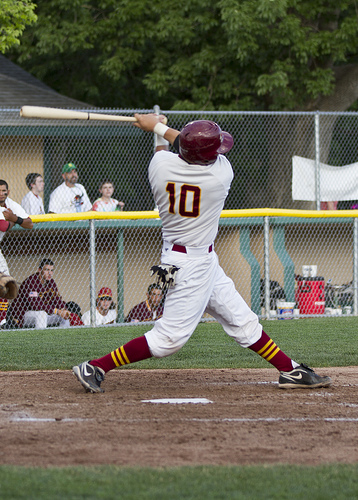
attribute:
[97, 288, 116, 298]
cap — red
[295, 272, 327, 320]
cooler — red 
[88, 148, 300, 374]
uniform — white, red, and yellow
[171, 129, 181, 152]
wristband — black 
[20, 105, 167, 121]
bat — wooden 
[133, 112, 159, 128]
hand — man's 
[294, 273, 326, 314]
cooler — black , red 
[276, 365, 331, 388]
baseball cleat — white baseball , black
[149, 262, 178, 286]
gloves — black, white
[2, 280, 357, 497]
field — baseball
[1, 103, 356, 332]
fence — chain link, silver, link, chain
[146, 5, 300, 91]
tree — large, green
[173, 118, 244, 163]
hat — red, hard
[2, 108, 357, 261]
fence — chain link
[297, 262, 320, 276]
cups — white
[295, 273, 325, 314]
water cooler — red, black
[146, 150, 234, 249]
jersey — baseball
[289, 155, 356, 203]
banner — white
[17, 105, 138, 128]
bat — light-colored, wooden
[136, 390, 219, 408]
plate — white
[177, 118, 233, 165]
helmet — burgundy,  dark red, for batting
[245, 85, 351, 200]
trunk — enormous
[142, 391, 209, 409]
plate — white home 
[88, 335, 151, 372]
sock — maroon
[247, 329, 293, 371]
sock — maroon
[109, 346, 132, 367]
stripes — yellow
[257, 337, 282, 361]
stripes — yellow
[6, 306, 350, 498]
field — baseball